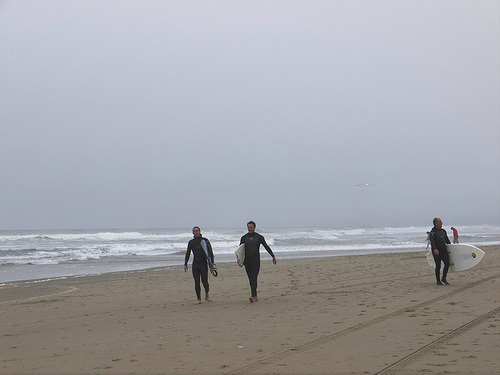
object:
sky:
[0, 0, 499, 230]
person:
[450, 226, 459, 244]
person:
[424, 231, 433, 251]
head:
[432, 217, 443, 230]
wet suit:
[430, 227, 452, 280]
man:
[428, 217, 452, 286]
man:
[184, 225, 215, 304]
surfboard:
[200, 238, 216, 268]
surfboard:
[427, 244, 486, 273]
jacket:
[452, 228, 458, 238]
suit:
[183, 235, 214, 301]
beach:
[0, 241, 500, 375]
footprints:
[292, 268, 394, 309]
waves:
[94, 222, 175, 251]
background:
[0, 0, 500, 257]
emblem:
[471, 251, 477, 260]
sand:
[0, 245, 500, 375]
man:
[236, 220, 277, 303]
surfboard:
[234, 243, 248, 267]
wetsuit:
[239, 231, 275, 297]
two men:
[182, 220, 277, 304]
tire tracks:
[233, 273, 500, 374]